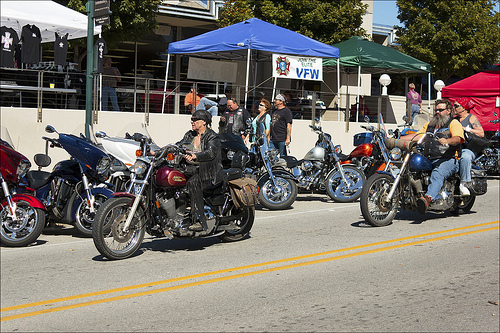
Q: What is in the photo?
A: Motorcycles.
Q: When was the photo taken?
A: Daytime.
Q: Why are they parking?
A: Stop over.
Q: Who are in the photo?
A: Bikers.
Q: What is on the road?
A: Yellow lines.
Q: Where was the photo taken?
A: At a motorcycle rally.